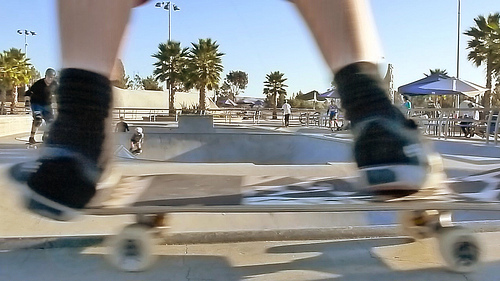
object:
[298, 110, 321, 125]
bicycle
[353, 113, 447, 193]
shoe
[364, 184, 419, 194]
shoe bottom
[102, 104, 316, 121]
fence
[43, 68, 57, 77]
helmet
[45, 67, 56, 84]
head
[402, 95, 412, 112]
man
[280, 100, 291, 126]
man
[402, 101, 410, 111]
shirt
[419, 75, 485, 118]
umbrella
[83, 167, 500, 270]
skateboard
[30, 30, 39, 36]
lights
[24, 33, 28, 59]
pole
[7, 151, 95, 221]
shoes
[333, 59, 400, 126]
black sock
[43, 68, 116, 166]
black sock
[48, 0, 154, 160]
legs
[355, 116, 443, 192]
foot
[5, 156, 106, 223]
foot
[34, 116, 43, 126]
knee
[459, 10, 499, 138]
tree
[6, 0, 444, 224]
person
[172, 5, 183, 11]
lights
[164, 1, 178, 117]
lamp post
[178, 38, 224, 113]
trees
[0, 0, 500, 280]
park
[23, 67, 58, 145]
kid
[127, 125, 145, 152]
kid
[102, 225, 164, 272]
wheel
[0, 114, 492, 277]
skatepark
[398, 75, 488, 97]
canopies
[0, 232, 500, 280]
ground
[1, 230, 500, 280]
shadow